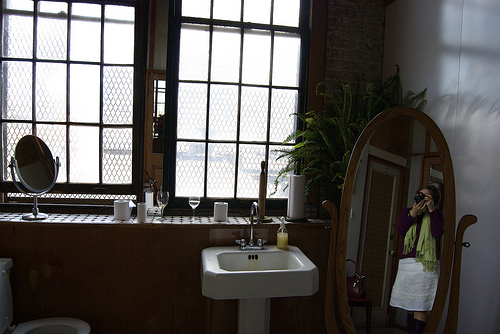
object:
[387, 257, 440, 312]
skirt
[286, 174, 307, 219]
paper towel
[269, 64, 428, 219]
plant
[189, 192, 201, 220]
glass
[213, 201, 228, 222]
toilet paper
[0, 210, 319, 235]
shelf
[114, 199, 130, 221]
paper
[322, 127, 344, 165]
ground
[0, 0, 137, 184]
window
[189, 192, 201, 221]
wine glasses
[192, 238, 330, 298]
sink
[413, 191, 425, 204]
camera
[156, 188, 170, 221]
wine glass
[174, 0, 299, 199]
window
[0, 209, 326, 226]
ledge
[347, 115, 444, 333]
reflection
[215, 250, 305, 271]
sink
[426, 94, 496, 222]
floor plant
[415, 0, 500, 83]
wall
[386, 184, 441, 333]
person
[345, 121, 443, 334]
mirror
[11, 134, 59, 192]
mirror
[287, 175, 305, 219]
towels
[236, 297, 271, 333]
pedestal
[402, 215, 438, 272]
scarf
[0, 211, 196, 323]
counter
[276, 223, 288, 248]
bottle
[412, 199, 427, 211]
hand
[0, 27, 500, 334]
picture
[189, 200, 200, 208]
liquid